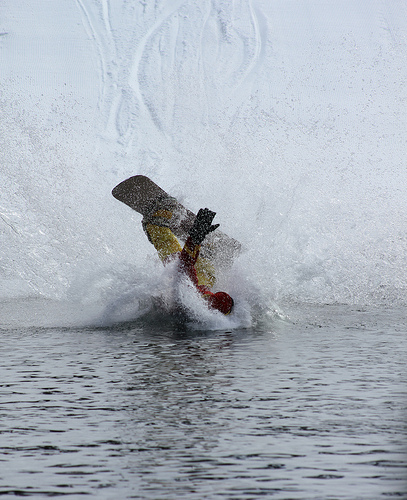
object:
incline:
[0, 0, 406, 309]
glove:
[177, 203, 222, 245]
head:
[206, 290, 237, 320]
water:
[0, 34, 406, 498]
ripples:
[0, 318, 406, 500]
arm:
[168, 241, 216, 281]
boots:
[142, 196, 180, 232]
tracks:
[75, 1, 188, 148]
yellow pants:
[140, 201, 189, 274]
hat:
[206, 290, 236, 321]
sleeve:
[176, 237, 203, 304]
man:
[131, 194, 235, 325]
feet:
[149, 198, 178, 230]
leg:
[141, 195, 189, 266]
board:
[109, 173, 245, 272]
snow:
[0, 2, 406, 304]